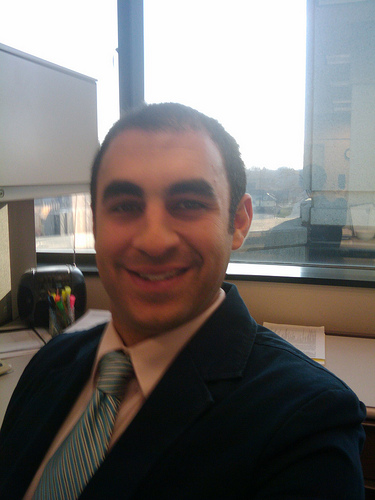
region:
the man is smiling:
[65, 101, 261, 315]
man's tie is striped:
[12, 347, 147, 498]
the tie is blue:
[28, 348, 169, 499]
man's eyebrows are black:
[76, 152, 228, 195]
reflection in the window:
[273, 141, 364, 243]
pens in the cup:
[40, 282, 87, 327]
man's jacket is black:
[20, 298, 366, 480]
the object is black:
[14, 242, 92, 326]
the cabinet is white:
[1, 32, 127, 190]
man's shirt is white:
[69, 303, 224, 391]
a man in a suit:
[1, 89, 369, 498]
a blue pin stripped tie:
[23, 346, 134, 498]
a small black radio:
[15, 265, 86, 327]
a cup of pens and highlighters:
[44, 283, 78, 336]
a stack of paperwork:
[261, 321, 325, 366]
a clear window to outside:
[0, 0, 372, 267]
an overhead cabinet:
[0, 40, 98, 202]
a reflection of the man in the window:
[251, 165, 343, 257]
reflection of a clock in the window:
[343, 146, 351, 157]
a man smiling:
[2, 99, 372, 498]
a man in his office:
[4, 97, 373, 460]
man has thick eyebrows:
[101, 177, 220, 225]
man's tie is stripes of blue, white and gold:
[59, 351, 135, 499]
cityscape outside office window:
[241, 86, 366, 267]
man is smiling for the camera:
[93, 119, 234, 334]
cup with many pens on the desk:
[43, 282, 77, 334]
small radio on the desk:
[15, 202, 87, 325]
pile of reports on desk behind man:
[262, 320, 328, 363]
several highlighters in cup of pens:
[45, 286, 76, 337]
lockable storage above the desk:
[1, 41, 97, 204]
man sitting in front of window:
[1, 1, 373, 499]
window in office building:
[1, 0, 373, 267]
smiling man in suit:
[0, 102, 373, 498]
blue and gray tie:
[31, 347, 135, 498]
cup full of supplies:
[45, 285, 75, 335]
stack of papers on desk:
[260, 320, 324, 362]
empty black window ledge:
[75, 264, 373, 288]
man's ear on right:
[232, 193, 253, 249]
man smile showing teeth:
[118, 260, 191, 290]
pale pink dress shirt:
[23, 287, 226, 498]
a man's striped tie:
[12, 347, 134, 498]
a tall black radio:
[18, 259, 88, 324]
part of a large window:
[135, 0, 373, 265]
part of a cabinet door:
[1, 69, 99, 185]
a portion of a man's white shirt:
[12, 284, 228, 498]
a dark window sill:
[39, 257, 373, 286]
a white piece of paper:
[263, 319, 328, 368]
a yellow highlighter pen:
[64, 286, 71, 301]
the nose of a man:
[132, 193, 183, 256]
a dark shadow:
[0, 293, 16, 323]